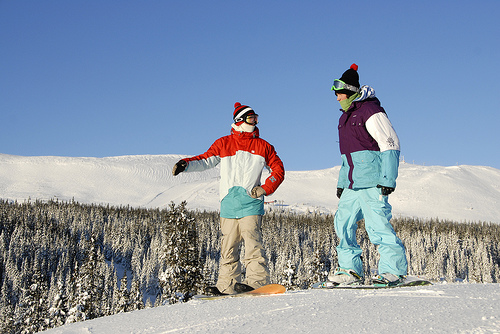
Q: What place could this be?
A: It is a forest.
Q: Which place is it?
A: It is a forest.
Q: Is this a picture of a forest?
A: Yes, it is showing a forest.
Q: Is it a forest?
A: Yes, it is a forest.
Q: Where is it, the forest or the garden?
A: It is the forest.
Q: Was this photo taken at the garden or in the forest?
A: It was taken at the forest.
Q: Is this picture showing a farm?
A: No, the picture is showing a forest.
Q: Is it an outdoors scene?
A: Yes, it is outdoors.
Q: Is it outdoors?
A: Yes, it is outdoors.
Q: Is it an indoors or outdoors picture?
A: It is outdoors.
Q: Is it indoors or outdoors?
A: It is outdoors.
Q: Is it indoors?
A: No, it is outdoors.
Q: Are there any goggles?
A: Yes, there are goggles.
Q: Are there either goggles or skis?
A: Yes, there are goggles.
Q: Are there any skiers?
A: No, there are no skiers.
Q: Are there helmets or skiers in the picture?
A: No, there are no skiers or helmets.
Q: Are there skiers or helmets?
A: No, there are no skiers or helmets.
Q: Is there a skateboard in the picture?
A: No, there are no skateboards.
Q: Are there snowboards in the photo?
A: Yes, there is a snowboard.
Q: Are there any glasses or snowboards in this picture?
A: Yes, there is a snowboard.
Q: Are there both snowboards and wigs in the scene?
A: No, there is a snowboard but no wigs.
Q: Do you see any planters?
A: No, there are no planters.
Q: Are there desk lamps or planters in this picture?
A: No, there are no planters or desk lamps.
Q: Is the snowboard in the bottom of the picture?
A: Yes, the snowboard is in the bottom of the image.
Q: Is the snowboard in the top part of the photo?
A: No, the snowboard is in the bottom of the image.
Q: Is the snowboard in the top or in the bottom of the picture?
A: The snowboard is in the bottom of the image.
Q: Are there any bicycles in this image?
A: No, there are no bicycles.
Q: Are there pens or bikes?
A: No, there are no bikes or pens.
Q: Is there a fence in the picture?
A: No, there are no fences.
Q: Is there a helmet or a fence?
A: No, there are no fences or helmets.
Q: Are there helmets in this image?
A: No, there are no helmets.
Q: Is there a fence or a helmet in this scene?
A: No, there are no helmets or fences.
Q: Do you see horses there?
A: No, there are no horses.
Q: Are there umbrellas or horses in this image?
A: No, there are no horses or umbrellas.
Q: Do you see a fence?
A: No, there are no fences.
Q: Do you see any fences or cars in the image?
A: No, there are no fences or cars.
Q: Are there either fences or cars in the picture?
A: No, there are no fences or cars.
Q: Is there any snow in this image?
A: Yes, there is snow.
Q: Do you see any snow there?
A: Yes, there is snow.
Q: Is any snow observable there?
A: Yes, there is snow.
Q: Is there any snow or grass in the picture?
A: Yes, there is snow.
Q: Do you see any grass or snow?
A: Yes, there is snow.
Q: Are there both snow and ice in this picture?
A: No, there is snow but no ice.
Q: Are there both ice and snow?
A: No, there is snow but no ice.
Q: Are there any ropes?
A: No, there are no ropes.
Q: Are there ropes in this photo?
A: No, there are no ropes.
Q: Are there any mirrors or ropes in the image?
A: No, there are no ropes or mirrors.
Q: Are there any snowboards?
A: Yes, there is a snowboard.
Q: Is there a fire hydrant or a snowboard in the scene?
A: Yes, there is a snowboard.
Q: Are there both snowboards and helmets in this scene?
A: No, there is a snowboard but no helmets.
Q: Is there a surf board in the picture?
A: No, there are no surfboards.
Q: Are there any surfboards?
A: No, there are no surfboards.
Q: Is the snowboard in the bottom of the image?
A: Yes, the snowboard is in the bottom of the image.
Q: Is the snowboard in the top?
A: No, the snowboard is in the bottom of the image.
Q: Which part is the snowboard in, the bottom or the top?
A: The snowboard is in the bottom of the image.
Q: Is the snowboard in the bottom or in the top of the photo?
A: The snowboard is in the bottom of the image.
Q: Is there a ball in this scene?
A: Yes, there is a ball.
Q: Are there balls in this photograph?
A: Yes, there is a ball.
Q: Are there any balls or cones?
A: Yes, there is a ball.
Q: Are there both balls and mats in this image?
A: No, there is a ball but no mats.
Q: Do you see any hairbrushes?
A: No, there are no hairbrushes.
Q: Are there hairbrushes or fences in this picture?
A: No, there are no hairbrushes or fences.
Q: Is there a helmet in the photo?
A: No, there are no helmets.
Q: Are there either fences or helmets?
A: No, there are no helmets or fences.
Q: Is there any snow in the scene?
A: Yes, there is snow.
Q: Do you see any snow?
A: Yes, there is snow.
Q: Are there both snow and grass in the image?
A: No, there is snow but no grass.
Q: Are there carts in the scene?
A: No, there are no carts.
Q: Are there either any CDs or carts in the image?
A: No, there are no carts or cds.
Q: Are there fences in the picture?
A: No, there are no fences.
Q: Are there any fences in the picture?
A: No, there are no fences.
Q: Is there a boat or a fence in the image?
A: No, there are no fences or boats.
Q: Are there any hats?
A: Yes, there is a hat.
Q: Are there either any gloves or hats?
A: Yes, there is a hat.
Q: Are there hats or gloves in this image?
A: Yes, there is a hat.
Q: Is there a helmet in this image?
A: No, there are no helmets.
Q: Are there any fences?
A: No, there are no fences.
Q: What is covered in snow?
A: The forest is covered in snow.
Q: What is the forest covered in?
A: The forest is covered in snow.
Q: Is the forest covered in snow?
A: Yes, the forest is covered in snow.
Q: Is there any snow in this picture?
A: Yes, there is snow.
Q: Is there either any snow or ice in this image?
A: Yes, there is snow.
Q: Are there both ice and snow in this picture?
A: No, there is snow but no ice.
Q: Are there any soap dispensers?
A: No, there are no soap dispensers.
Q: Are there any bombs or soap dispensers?
A: No, there are no soap dispensers or bombs.